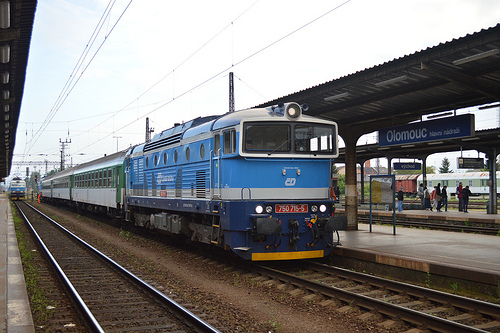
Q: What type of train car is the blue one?
A: Engine.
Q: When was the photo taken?
A: During the daytime.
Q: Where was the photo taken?
A: Outside somewhere.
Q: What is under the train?
A: Tracks.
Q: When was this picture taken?
A: Daytime.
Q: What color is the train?
A: Blue.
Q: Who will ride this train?
A: People.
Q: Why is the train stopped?
A: Pick up people.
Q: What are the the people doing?
A: Waiting to get on the train.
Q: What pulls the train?
A: Engine.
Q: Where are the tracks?
A: On the ground.